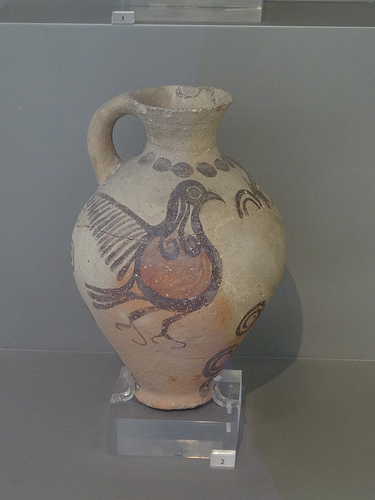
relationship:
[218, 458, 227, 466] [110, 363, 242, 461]
2 near base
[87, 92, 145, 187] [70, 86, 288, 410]
handle on pot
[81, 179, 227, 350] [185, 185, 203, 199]
bird has an eye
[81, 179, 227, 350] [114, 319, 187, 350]
bird has feet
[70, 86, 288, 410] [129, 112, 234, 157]
pot has a neck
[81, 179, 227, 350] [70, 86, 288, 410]
bird on pot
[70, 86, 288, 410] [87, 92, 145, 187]
pot has a handle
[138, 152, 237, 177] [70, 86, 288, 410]
black dots on pot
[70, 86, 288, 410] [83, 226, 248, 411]
pot has orange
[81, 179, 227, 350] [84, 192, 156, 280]
bird has wings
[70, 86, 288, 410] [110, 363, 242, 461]
pot on base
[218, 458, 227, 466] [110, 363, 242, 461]
2 on base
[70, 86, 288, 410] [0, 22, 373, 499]
pot in display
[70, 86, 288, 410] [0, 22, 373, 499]
pot on display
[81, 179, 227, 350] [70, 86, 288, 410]
bird painted on pot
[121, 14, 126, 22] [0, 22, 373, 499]
1 on display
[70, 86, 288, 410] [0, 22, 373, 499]
pot sitting in display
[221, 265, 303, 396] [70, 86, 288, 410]
shadow from pot